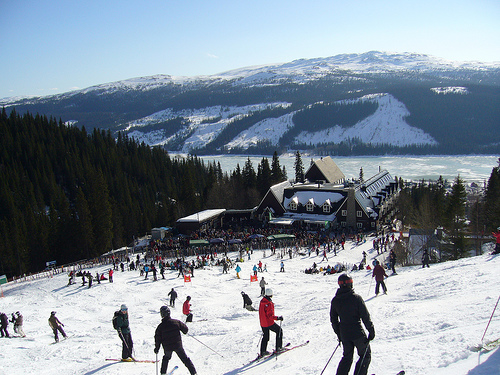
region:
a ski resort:
[45, 148, 497, 374]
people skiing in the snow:
[34, 254, 397, 374]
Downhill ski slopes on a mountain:
[135, 97, 455, 164]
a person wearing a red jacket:
[255, 293, 282, 333]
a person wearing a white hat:
[260, 283, 276, 302]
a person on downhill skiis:
[238, 325, 313, 372]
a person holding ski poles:
[245, 312, 292, 361]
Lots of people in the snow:
[59, 243, 392, 286]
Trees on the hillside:
[5, 94, 202, 254]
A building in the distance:
[165, 140, 430, 257]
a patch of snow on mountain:
[239, 111, 290, 161]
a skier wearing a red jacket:
[246, 284, 298, 374]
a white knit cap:
[261, 285, 276, 301]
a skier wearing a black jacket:
[309, 272, 368, 374]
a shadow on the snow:
[463, 348, 490, 373]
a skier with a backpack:
[102, 296, 132, 363]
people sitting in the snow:
[305, 258, 367, 275]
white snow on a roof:
[291, 188, 349, 210]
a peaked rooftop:
[304, 152, 343, 182]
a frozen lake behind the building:
[211, 142, 486, 177]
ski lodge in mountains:
[187, 158, 401, 239]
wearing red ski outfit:
[249, 288, 312, 364]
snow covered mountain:
[124, 100, 433, 156]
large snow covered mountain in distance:
[102, 52, 493, 73]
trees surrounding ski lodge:
[0, 105, 496, 277]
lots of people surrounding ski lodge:
[4, 227, 431, 373]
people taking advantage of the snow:
[2, 236, 440, 373]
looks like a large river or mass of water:
[166, 150, 494, 188]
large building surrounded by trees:
[147, 156, 401, 240]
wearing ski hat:
[111, 303, 137, 360]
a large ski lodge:
[138, 157, 395, 247]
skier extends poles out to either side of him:
[138, 304, 225, 374]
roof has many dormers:
[281, 167, 401, 216]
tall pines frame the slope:
[0, 112, 292, 295]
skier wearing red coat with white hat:
[211, 281, 314, 374]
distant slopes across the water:
[21, 42, 493, 146]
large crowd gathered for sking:
[1, 225, 408, 374]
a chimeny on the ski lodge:
[336, 187, 364, 236]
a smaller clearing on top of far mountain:
[414, 72, 490, 118]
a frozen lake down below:
[170, 144, 499, 189]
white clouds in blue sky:
[15, 19, 46, 57]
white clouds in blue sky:
[98, 20, 151, 69]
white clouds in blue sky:
[203, 16, 234, 52]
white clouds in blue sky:
[293, 12, 341, 37]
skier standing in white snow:
[316, 267, 367, 372]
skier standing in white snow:
[226, 295, 283, 360]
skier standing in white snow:
[151, 307, 186, 367]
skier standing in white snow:
[96, 297, 141, 370]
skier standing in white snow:
[30, 305, 68, 350]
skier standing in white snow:
[7, 302, 34, 348]